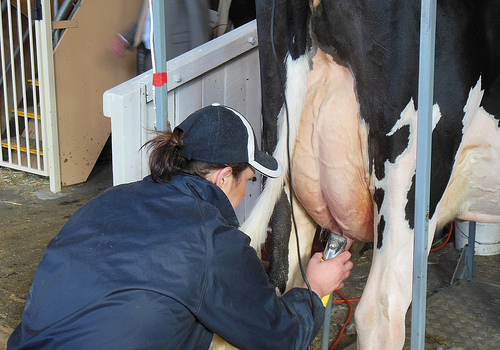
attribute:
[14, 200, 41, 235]
floor — clean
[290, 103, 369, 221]
glands — mammary glands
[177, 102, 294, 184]
cap — black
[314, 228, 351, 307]
device — milking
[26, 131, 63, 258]
floor — grey